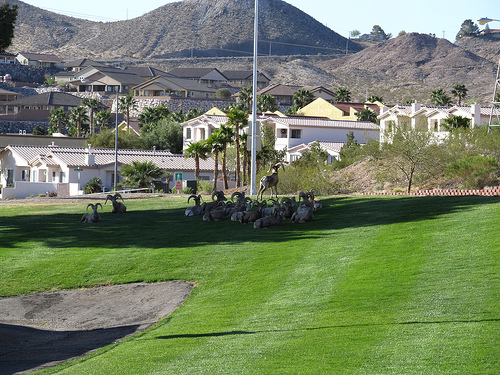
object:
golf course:
[0, 193, 500, 375]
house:
[375, 104, 499, 152]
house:
[0, 141, 231, 199]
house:
[247, 112, 380, 168]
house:
[132, 74, 217, 99]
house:
[0, 91, 110, 134]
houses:
[58, 63, 147, 93]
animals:
[256, 162, 285, 201]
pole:
[247, 0, 258, 195]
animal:
[80, 203, 103, 224]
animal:
[105, 191, 127, 214]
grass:
[0, 192, 500, 375]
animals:
[176, 188, 324, 235]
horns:
[86, 203, 104, 211]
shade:
[0, 193, 499, 249]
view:
[0, 0, 500, 109]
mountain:
[0, 0, 499, 108]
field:
[0, 0, 500, 375]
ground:
[0, 193, 500, 375]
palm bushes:
[117, 159, 171, 194]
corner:
[104, 193, 124, 204]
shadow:
[0, 321, 142, 375]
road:
[0, 278, 198, 375]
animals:
[184, 191, 323, 230]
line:
[154, 317, 499, 339]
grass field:
[0, 194, 500, 375]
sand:
[0, 297, 105, 341]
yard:
[0, 185, 500, 375]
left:
[1, 0, 131, 375]